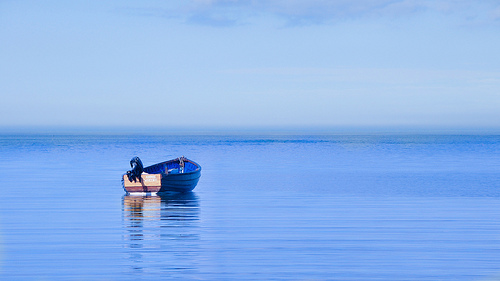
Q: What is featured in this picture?
A: A boat.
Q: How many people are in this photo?
A: None.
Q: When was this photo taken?
A: Daytime.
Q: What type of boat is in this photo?
A: A motorboat.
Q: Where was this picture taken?
A: The sea.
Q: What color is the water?
A: Blue.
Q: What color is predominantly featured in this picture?
A: Blue.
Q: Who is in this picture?
A: No one.